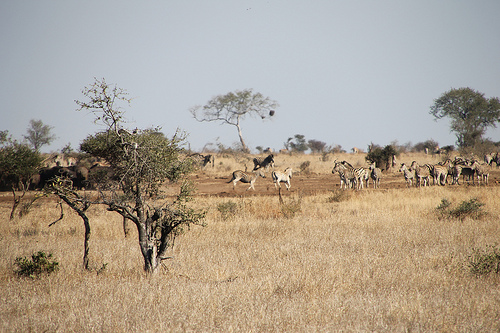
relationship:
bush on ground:
[13, 251, 59, 277] [2, 151, 498, 332]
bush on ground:
[218, 200, 238, 221] [2, 151, 498, 332]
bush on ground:
[274, 197, 301, 218] [2, 151, 498, 332]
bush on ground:
[330, 188, 352, 203] [2, 151, 498, 332]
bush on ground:
[437, 196, 489, 219] [2, 151, 498, 332]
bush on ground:
[467, 245, 499, 278] [2, 151, 498, 332]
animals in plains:
[223, 153, 499, 188] [0, 1, 496, 333]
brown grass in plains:
[3, 152, 499, 332] [0, 1, 496, 333]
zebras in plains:
[224, 153, 498, 189] [0, 1, 496, 333]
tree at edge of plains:
[428, 85, 499, 144] [0, 1, 496, 333]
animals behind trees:
[28, 163, 99, 187] [1, 77, 210, 269]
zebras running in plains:
[224, 153, 498, 189] [0, 1, 496, 333]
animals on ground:
[223, 153, 499, 188] [2, 151, 498, 332]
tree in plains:
[189, 91, 281, 152] [0, 1, 496, 333]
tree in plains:
[428, 85, 499, 144] [0, 1, 496, 333]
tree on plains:
[189, 91, 281, 152] [0, 1, 496, 333]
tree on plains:
[428, 85, 499, 144] [0, 1, 496, 333]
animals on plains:
[223, 153, 499, 188] [0, 1, 496, 333]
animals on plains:
[28, 163, 99, 187] [0, 1, 496, 333]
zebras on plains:
[224, 153, 498, 189] [0, 1, 496, 333]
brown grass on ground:
[3, 152, 499, 332] [2, 151, 498, 332]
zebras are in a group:
[224, 153, 498, 189] [223, 153, 499, 188]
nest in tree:
[129, 141, 140, 148] [86, 80, 212, 273]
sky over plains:
[0, 1, 498, 154] [0, 1, 496, 333]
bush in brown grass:
[13, 251, 59, 277] [3, 152, 499, 332]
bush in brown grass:
[218, 200, 238, 221] [3, 152, 499, 332]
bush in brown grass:
[274, 197, 301, 218] [3, 152, 499, 332]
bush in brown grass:
[330, 188, 352, 203] [3, 152, 499, 332]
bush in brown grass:
[437, 196, 489, 219] [3, 152, 499, 332]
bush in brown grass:
[467, 245, 499, 278] [3, 152, 499, 332]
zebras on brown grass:
[224, 153, 498, 189] [3, 152, 499, 332]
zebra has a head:
[226, 164, 267, 190] [257, 167, 266, 179]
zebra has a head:
[271, 166, 295, 187] [285, 165, 294, 180]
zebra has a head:
[331, 161, 364, 187] [332, 162, 343, 174]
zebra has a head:
[398, 163, 415, 185] [398, 163, 409, 176]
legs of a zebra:
[232, 178, 257, 191] [226, 164, 267, 190]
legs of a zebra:
[273, 180, 291, 191] [271, 166, 295, 187]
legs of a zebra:
[342, 175, 365, 186] [331, 161, 364, 187]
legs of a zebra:
[407, 179, 417, 185] [398, 163, 415, 185]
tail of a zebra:
[225, 172, 234, 182] [226, 164, 267, 190]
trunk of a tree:
[236, 125, 249, 150] [189, 91, 281, 152]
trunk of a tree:
[134, 224, 167, 271] [86, 80, 212, 273]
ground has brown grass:
[2, 151, 498, 332] [3, 152, 499, 332]